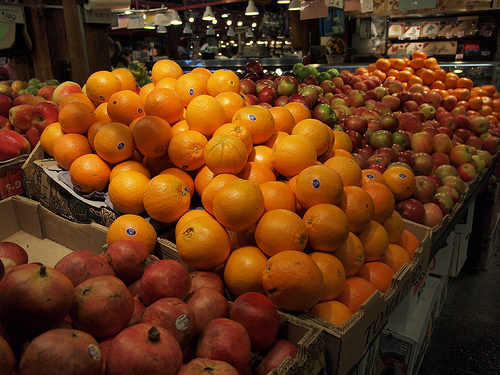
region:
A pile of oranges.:
[78, 61, 373, 296]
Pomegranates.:
[25, 235, 230, 370]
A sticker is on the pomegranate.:
[155, 300, 195, 340]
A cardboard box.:
[6, 187, 76, 257]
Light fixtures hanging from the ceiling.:
[132, 0, 282, 40]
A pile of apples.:
[310, 80, 425, 155]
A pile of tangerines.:
[370, 50, 497, 110]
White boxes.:
[386, 256, 457, 371]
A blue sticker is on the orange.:
[305, 170, 325, 194]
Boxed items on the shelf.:
[385, 16, 490, 56]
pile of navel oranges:
[102, 73, 259, 214]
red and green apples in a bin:
[286, 71, 426, 156]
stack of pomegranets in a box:
[8, 241, 264, 370]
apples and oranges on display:
[95, 68, 415, 243]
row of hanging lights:
[109, 0, 273, 45]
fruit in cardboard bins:
[293, 123, 487, 347]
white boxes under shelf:
[377, 158, 483, 360]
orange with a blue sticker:
[294, 163, 347, 211]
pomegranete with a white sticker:
[150, 298, 200, 340]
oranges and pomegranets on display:
[90, 103, 295, 357]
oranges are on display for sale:
[56, 57, 423, 329]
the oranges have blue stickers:
[233, 106, 272, 142]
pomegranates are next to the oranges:
[0, 204, 292, 374]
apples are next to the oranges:
[240, 57, 492, 227]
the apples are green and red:
[246, 69, 483, 226]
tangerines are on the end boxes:
[358, 53, 498, 133]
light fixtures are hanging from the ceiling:
[113, 2, 298, 41]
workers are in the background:
[130, 35, 200, 72]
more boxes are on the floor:
[386, 200, 485, 367]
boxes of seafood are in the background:
[383, 12, 494, 67]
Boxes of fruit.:
[0, 69, 474, 374]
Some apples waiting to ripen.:
[367, 108, 409, 158]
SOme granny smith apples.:
[26, 78, 46, 93]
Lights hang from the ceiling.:
[153, 1, 261, 27]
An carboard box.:
[11, 190, 83, 261]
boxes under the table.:
[380, 241, 488, 374]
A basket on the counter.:
[323, 35, 348, 62]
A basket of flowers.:
[320, 36, 349, 65]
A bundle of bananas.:
[123, 55, 151, 83]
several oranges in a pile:
[79, 65, 376, 285]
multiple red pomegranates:
[12, 249, 250, 373]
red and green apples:
[279, 68, 469, 208]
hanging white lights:
[123, 2, 294, 22]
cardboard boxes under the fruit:
[386, 262, 474, 354]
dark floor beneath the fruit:
[469, 283, 498, 365]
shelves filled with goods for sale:
[381, 5, 498, 59]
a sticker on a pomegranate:
[177, 314, 191, 328]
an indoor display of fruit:
[5, 51, 477, 371]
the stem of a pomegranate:
[140, 325, 165, 342]